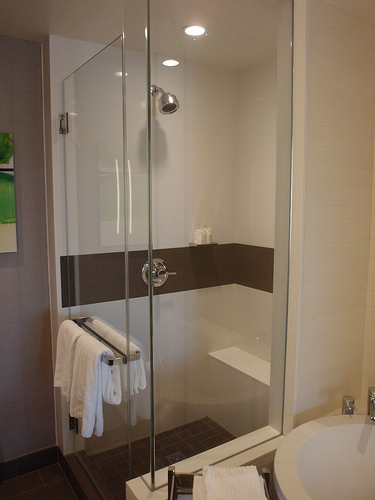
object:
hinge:
[57, 107, 69, 135]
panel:
[60, 29, 125, 480]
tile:
[89, 415, 236, 497]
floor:
[1, 462, 75, 499]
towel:
[189, 462, 266, 499]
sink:
[271, 411, 373, 499]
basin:
[327, 471, 374, 499]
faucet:
[365, 384, 374, 422]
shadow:
[356, 416, 375, 453]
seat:
[205, 347, 269, 437]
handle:
[73, 318, 118, 369]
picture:
[0, 133, 15, 251]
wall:
[0, 37, 56, 465]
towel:
[70, 330, 120, 439]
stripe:
[61, 242, 282, 308]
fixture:
[150, 84, 179, 116]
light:
[163, 57, 178, 69]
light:
[183, 23, 204, 38]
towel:
[48, 316, 82, 398]